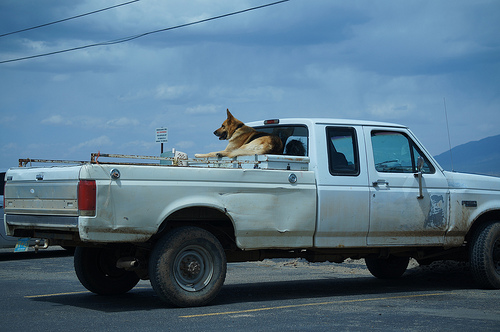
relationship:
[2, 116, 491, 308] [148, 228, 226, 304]
truck has a tire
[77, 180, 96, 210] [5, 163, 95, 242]
brake light in rear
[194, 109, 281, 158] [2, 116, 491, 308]
dog in truck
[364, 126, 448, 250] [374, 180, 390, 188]
door has a handle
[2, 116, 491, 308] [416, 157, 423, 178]
truck has a mirror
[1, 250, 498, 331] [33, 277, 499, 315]
ground has a shadow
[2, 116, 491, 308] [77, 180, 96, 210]
truck has a brake light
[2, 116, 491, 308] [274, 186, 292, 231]
truck has a dent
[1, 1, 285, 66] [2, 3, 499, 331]
wire in air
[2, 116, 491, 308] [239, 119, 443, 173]
truck has a top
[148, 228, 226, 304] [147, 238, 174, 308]
tire has mud